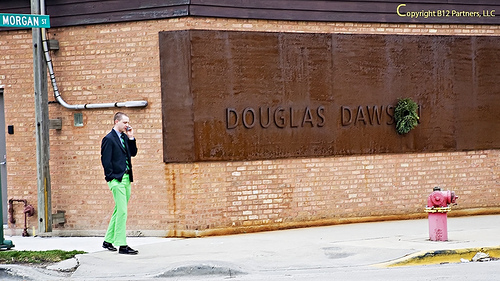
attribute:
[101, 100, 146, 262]
man — using a phone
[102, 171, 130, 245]
pants — green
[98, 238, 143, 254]
shoes — black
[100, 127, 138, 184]
jacket — black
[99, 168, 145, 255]
trousers — green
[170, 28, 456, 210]
building — red, brick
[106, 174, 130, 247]
pants — green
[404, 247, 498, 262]
sidewalk — yellow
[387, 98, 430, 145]
wreath — green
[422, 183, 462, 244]
hydrant — red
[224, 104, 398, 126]
name — Douglas Daws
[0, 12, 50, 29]
sign — green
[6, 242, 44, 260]
grass — a patch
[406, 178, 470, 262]
fire hydrant — red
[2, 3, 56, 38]
sign — green and white, street